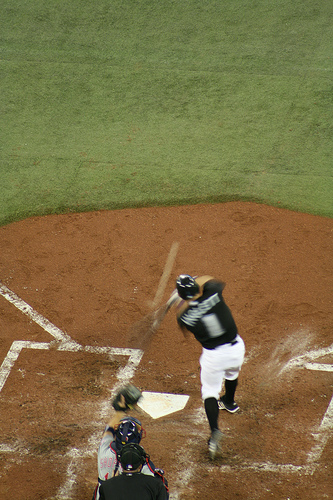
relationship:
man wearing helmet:
[174, 271, 246, 461] [175, 273, 200, 302]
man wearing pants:
[174, 271, 246, 461] [199, 328, 245, 400]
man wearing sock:
[174, 271, 246, 461] [204, 393, 219, 438]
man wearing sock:
[174, 271, 246, 461] [223, 377, 239, 407]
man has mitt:
[96, 385, 161, 491] [110, 382, 141, 410]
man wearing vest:
[96, 385, 161, 491] [110, 442, 154, 473]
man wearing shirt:
[174, 271, 246, 461] [177, 277, 238, 349]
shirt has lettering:
[177, 277, 238, 349] [182, 291, 224, 329]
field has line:
[2, 2, 332, 499] [1, 281, 149, 499]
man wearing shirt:
[96, 385, 161, 491] [177, 277, 238, 349]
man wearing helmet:
[96, 385, 161, 491] [116, 419, 143, 445]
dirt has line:
[2, 197, 329, 500] [1, 281, 149, 499]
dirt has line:
[2, 197, 329, 500] [168, 332, 332, 500]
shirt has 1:
[177, 277, 238, 349] [202, 314, 225, 342]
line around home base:
[1, 281, 149, 499] [133, 389, 192, 422]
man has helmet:
[174, 271, 246, 461] [175, 273, 200, 302]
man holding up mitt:
[96, 385, 161, 491] [110, 382, 141, 410]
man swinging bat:
[174, 271, 246, 461] [132, 294, 179, 345]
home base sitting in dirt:
[133, 389, 192, 422] [2, 197, 329, 500]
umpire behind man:
[99, 446, 169, 499] [96, 385, 161, 491]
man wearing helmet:
[96, 385, 161, 491] [175, 273, 200, 302]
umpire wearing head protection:
[99, 446, 169, 499] [117, 442, 149, 474]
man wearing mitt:
[96, 385, 161, 491] [110, 382, 141, 410]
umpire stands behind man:
[99, 446, 169, 499] [96, 385, 161, 491]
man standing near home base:
[174, 271, 246, 461] [133, 389, 192, 422]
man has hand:
[174, 271, 246, 461] [172, 287, 183, 301]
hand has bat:
[172, 287, 183, 301] [132, 294, 179, 345]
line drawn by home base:
[1, 281, 149, 499] [133, 389, 192, 422]